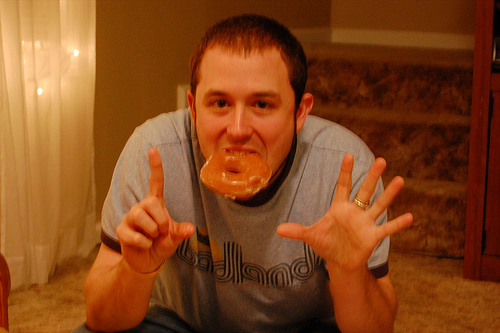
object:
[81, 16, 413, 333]
man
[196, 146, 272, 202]
doughnut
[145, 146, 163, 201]
finger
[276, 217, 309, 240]
finger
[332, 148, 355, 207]
finger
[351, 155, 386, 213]
finger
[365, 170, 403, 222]
finger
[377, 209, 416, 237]
finger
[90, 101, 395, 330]
shirt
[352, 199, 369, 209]
ring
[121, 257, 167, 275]
band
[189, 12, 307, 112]
hair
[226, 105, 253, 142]
nose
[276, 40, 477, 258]
steps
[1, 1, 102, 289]
curtains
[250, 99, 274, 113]
eyes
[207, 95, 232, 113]
eyes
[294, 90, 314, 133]
ear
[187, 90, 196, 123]
ear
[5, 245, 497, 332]
carpet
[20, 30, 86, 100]
lamp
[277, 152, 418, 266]
5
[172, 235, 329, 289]
logo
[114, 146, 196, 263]
hand